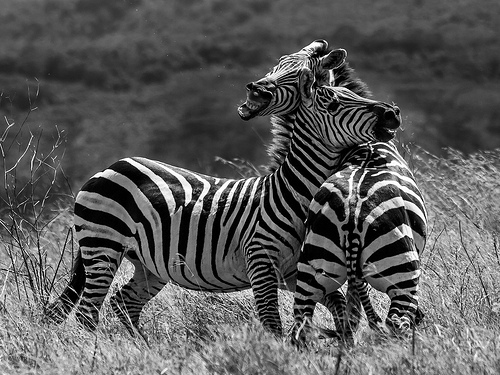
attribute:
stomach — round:
[146, 255, 248, 295]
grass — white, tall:
[0, 96, 53, 374]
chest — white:
[265, 212, 311, 289]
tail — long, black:
[347, 237, 382, 331]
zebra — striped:
[237, 39, 430, 340]